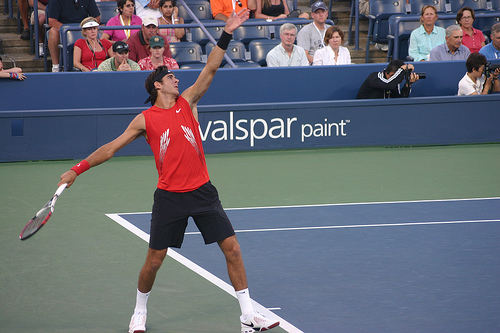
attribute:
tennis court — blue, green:
[107, 194, 499, 331]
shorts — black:
[149, 180, 236, 250]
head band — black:
[153, 66, 174, 81]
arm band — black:
[213, 26, 236, 48]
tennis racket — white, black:
[16, 179, 68, 241]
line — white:
[244, 195, 498, 240]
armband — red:
[71, 160, 90, 174]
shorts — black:
[141, 186, 243, 262]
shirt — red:
[135, 97, 213, 191]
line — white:
[109, 192, 496, 217]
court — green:
[15, 145, 497, 324]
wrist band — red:
[63, 132, 95, 179]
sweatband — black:
[141, 58, 173, 103]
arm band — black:
[215, 30, 232, 47]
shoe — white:
[235, 307, 287, 329]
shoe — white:
[124, 309, 152, 331]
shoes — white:
[235, 306, 279, 331]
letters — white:
[196, 109, 353, 152]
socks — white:
[234, 284, 252, 319]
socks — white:
[128, 281, 153, 320]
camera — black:
[403, 66, 426, 80]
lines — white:
[275, 217, 380, 241]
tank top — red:
[140, 89, 215, 192]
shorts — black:
[144, 179, 244, 250]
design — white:
[154, 119, 198, 172]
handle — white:
[61, 204, 74, 237]